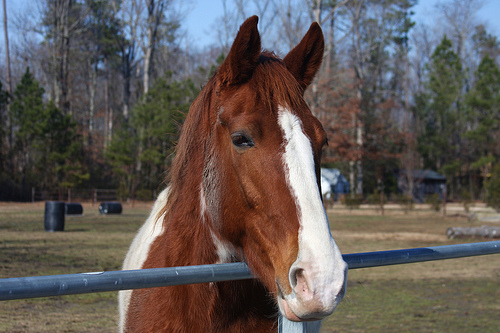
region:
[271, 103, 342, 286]
white marking on a horse's face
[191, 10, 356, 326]
head of a horse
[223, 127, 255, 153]
right eye of a horse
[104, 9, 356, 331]
a horse by a rail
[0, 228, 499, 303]
grey colored rail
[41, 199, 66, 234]
black barrel standing upright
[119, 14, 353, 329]
a pointy eared horse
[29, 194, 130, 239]
barrels for horse feeding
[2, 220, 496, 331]
metal railing outside a farm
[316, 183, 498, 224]
a row of farm crops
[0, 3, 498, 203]
a forest surrounding a farm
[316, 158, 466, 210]
blue barn and house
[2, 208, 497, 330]
a grassy field filled with farming equipment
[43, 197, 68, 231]
a large black barrel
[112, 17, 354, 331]
a brown and white horse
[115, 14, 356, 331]
a horse leaning over fence railing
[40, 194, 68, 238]
a black barrel sized trash can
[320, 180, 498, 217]
a row of crops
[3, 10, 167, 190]
a large tall tree forest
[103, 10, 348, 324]
a brown and white horse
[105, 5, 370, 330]
a horse with pointy ears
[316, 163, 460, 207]
a white house and a barn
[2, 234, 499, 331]
a fence post in a farm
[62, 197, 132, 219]
animal feeding and water cans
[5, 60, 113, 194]
a large green tree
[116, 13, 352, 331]
a brown and white horse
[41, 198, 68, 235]
a black barrel in the grass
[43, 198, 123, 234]
a trio of barrels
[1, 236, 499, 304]
the top rail of a fence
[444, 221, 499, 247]
a log in the grass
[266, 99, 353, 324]
a diamond patter on a horses nose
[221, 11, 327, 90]
a horses ears perked up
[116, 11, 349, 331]
a horse near a fence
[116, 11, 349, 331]
a horse in a field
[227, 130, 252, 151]
Eye on a horse's face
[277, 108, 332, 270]
White blaze on horse's head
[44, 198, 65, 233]
Black barrel in a corral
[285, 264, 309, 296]
Nostril on horse's nose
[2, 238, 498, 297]
Gray metal fence pole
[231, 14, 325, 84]
Brown ears on a horse's head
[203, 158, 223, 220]
Patch of dirty fur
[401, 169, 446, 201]
Small brown building near corral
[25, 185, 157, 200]
Wooden fence on far side of corral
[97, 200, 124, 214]
Fallen barrel in a field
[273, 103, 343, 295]
white blaze on a chestnut face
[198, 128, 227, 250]
dried dirt on the cheek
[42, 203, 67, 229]
black barrel to mark a riding path